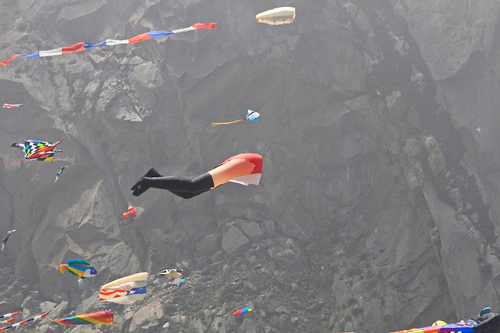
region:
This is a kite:
[203, 97, 287, 132]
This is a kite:
[117, 200, 160, 230]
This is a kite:
[226, 295, 261, 322]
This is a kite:
[156, 260, 211, 295]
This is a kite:
[58, 249, 100, 287]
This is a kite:
[0, 220, 20, 252]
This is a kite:
[43, 303, 115, 332]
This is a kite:
[246, 2, 311, 35]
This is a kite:
[11, 134, 88, 200]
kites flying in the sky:
[0, 0, 495, 331]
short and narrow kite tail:
[203, 107, 247, 136]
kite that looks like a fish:
[55, 254, 103, 286]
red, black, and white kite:
[109, 138, 287, 204]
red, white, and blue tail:
[2, 12, 226, 72]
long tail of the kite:
[2, 4, 227, 84]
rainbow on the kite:
[49, 309, 121, 328]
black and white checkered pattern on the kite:
[18, 138, 58, 154]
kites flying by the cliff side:
[1, 0, 498, 332]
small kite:
[1, 99, 26, 109]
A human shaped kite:
[232, 155, 260, 173]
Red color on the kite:
[256, 156, 263, 171]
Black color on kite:
[162, 177, 189, 189]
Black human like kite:
[172, 180, 203, 189]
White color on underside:
[242, 176, 259, 182]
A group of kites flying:
[0, 311, 15, 328]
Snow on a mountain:
[37, 81, 67, 99]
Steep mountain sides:
[63, 206, 110, 248]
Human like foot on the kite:
[140, 177, 146, 189]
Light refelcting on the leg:
[178, 178, 198, 180]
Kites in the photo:
[55, 27, 147, 97]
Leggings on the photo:
[157, 143, 197, 203]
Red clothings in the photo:
[241, 153, 267, 190]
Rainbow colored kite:
[52, 305, 104, 331]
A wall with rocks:
[327, 110, 412, 230]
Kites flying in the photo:
[20, 124, 70, 183]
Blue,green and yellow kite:
[62, 248, 109, 288]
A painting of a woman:
[139, 135, 249, 206]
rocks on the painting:
[197, 266, 268, 331]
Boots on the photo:
[113, 161, 154, 196]